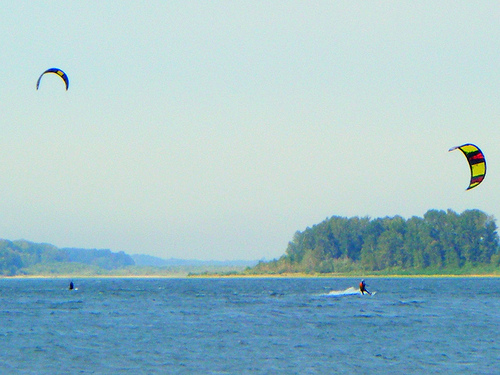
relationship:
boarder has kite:
[69, 281, 74, 290] [35, 68, 69, 91]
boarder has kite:
[358, 279, 371, 296] [448, 143, 488, 192]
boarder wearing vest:
[358, 279, 371, 296] [359, 282, 364, 288]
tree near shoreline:
[284, 224, 315, 265] [0, 273, 498, 280]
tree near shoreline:
[359, 236, 378, 271] [0, 273, 498, 280]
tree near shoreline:
[375, 230, 402, 270] [0, 273, 498, 280]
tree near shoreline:
[454, 210, 486, 240] [0, 273, 498, 280]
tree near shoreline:
[479, 220, 499, 243] [0, 273, 498, 280]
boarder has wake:
[358, 279, 371, 296] [326, 286, 368, 295]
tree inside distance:
[284, 224, 315, 265] [1, 208, 500, 278]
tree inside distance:
[359, 236, 378, 271] [1, 208, 500, 278]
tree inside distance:
[375, 230, 402, 270] [1, 208, 500, 278]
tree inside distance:
[454, 210, 486, 240] [1, 208, 500, 278]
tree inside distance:
[479, 220, 499, 243] [1, 208, 500, 278]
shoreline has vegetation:
[186, 273, 499, 279] [188, 208, 499, 276]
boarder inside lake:
[69, 281, 74, 290] [0, 276, 499, 374]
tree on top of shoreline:
[284, 224, 315, 265] [0, 273, 498, 280]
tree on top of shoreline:
[359, 236, 378, 271] [0, 273, 498, 280]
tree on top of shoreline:
[375, 230, 402, 270] [0, 273, 498, 280]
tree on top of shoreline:
[454, 210, 486, 240] [0, 273, 498, 280]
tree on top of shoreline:
[479, 220, 499, 243] [0, 273, 498, 280]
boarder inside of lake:
[69, 281, 74, 290] [0, 276, 499, 374]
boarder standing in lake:
[69, 281, 74, 290] [0, 276, 499, 374]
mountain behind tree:
[133, 254, 268, 267] [284, 224, 315, 265]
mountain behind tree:
[133, 254, 268, 267] [359, 236, 378, 271]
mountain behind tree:
[133, 254, 268, 267] [375, 230, 402, 270]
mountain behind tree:
[133, 254, 268, 267] [454, 210, 486, 240]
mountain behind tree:
[133, 254, 268, 267] [479, 220, 499, 243]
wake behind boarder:
[326, 286, 368, 295] [358, 279, 371, 296]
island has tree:
[0, 208, 499, 279] [284, 224, 315, 265]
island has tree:
[0, 208, 499, 279] [359, 236, 378, 271]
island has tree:
[0, 208, 499, 279] [375, 230, 402, 270]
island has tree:
[0, 208, 499, 279] [454, 210, 486, 240]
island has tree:
[0, 208, 499, 279] [479, 220, 499, 243]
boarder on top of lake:
[69, 281, 74, 290] [0, 276, 499, 374]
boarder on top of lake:
[358, 279, 371, 296] [0, 276, 499, 374]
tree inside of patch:
[284, 224, 315, 265] [286, 208, 500, 276]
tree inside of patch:
[359, 236, 378, 271] [286, 208, 500, 276]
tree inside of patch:
[375, 230, 402, 270] [286, 208, 500, 276]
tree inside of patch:
[454, 210, 486, 240] [286, 208, 500, 276]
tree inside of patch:
[479, 220, 499, 243] [286, 208, 500, 276]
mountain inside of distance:
[133, 254, 268, 267] [1, 208, 500, 278]